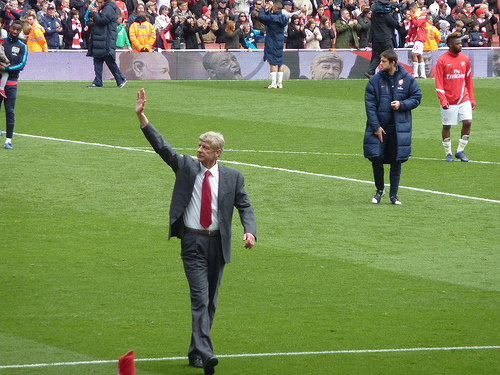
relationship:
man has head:
[131, 86, 263, 368] [195, 132, 225, 165]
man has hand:
[131, 86, 263, 368] [136, 91, 150, 127]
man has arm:
[131, 86, 263, 368] [136, 95, 179, 165]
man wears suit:
[131, 86, 263, 368] [151, 122, 258, 360]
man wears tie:
[131, 86, 263, 368] [203, 175, 212, 231]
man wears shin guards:
[436, 35, 473, 160] [444, 137, 473, 145]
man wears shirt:
[131, 86, 263, 368] [185, 159, 220, 231]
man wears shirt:
[436, 35, 473, 160] [433, 56, 473, 107]